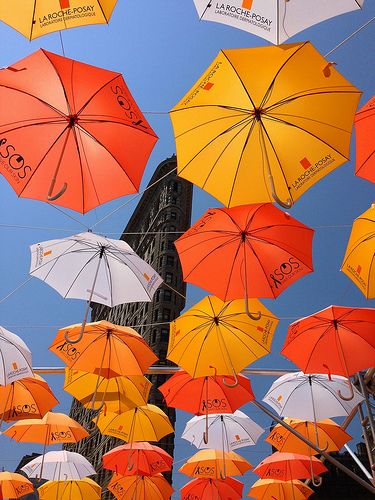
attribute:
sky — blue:
[277, 196, 367, 311]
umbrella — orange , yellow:
[62, 365, 152, 415]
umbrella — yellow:
[90, 402, 174, 442]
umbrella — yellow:
[147, 286, 287, 400]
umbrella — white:
[158, 42, 373, 189]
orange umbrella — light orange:
[51, 318, 158, 381]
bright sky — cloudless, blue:
[119, 3, 193, 71]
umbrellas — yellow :
[174, 42, 356, 207]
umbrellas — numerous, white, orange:
[1, 3, 373, 499]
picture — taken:
[19, 8, 372, 498]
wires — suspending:
[0, 19, 375, 342]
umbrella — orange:
[184, 196, 318, 305]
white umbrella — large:
[28, 228, 157, 319]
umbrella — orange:
[279, 303, 373, 378]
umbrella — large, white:
[152, 21, 362, 211]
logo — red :
[285, 149, 336, 194]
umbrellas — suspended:
[265, 303, 373, 425]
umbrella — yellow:
[159, 36, 357, 210]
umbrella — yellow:
[162, 296, 279, 382]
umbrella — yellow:
[176, 448, 252, 479]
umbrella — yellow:
[5, 412, 88, 444]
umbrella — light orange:
[151, 65, 370, 239]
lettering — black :
[272, 258, 300, 282]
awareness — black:
[271, 262, 297, 287]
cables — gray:
[11, 125, 281, 380]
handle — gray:
[237, 285, 262, 325]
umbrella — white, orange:
[26, 218, 172, 350]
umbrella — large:
[159, 288, 281, 395]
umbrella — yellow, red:
[161, 290, 284, 388]